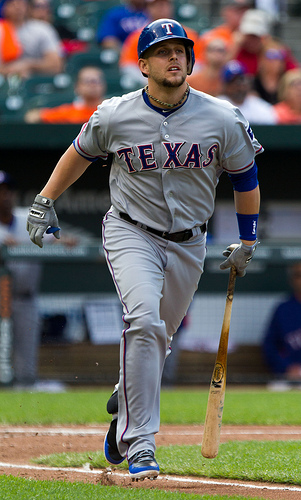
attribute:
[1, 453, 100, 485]
line — white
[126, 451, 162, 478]
shoe — blue, white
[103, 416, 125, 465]
shoe — blue, white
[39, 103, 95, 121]
shirt — orange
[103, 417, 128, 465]
shoe — blue, black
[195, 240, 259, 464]
bat — wooden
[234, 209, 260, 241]
sweat band — blue colored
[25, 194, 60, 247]
glove — grey, white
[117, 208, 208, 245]
belt — baseball, black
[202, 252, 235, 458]
wooden bat — large , wooden 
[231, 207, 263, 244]
arm band — white, blue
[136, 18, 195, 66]
hat — blue